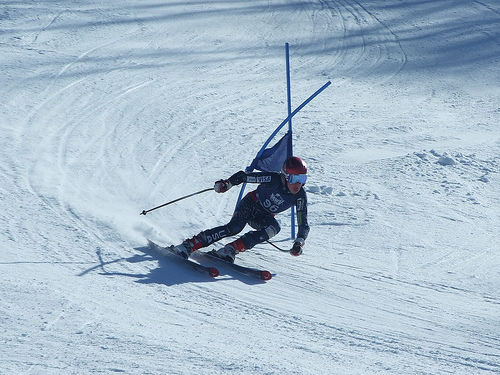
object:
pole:
[136, 185, 226, 219]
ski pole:
[138, 180, 216, 239]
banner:
[237, 41, 331, 194]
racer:
[167, 156, 310, 263]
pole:
[266, 236, 293, 254]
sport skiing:
[388, 76, 475, 221]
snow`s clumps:
[308, 144, 498, 216]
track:
[304, 0, 407, 91]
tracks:
[35, 88, 178, 184]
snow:
[339, 65, 481, 310]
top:
[234, 171, 317, 230]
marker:
[193, 122, 347, 251]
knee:
[269, 222, 281, 233]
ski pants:
[182, 195, 281, 269]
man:
[174, 154, 310, 261]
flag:
[247, 129, 292, 174]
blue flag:
[247, 129, 292, 173]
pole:
[283, 41, 296, 238]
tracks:
[10, 55, 193, 185]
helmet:
[284, 156, 312, 183]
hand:
[211, 174, 234, 196]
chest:
[236, 177, 312, 237]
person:
[192, 156, 322, 278]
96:
[262, 197, 278, 214]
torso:
[253, 177, 291, 212]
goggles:
[280, 172, 307, 184]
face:
[284, 175, 302, 194]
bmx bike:
[19, 47, 144, 210]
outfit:
[182, 169, 311, 251]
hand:
[286, 242, 308, 257]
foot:
[210, 247, 235, 263]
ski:
[220, 247, 270, 275]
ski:
[147, 239, 215, 278]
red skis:
[192, 249, 277, 281]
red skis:
[145, 240, 217, 275]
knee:
[224, 222, 247, 236]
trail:
[17, 4, 496, 366]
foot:
[168, 242, 187, 254]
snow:
[1, 2, 181, 215]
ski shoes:
[144, 240, 199, 268]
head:
[282, 152, 307, 196]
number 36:
[263, 198, 279, 213]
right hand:
[212, 177, 231, 195]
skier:
[170, 155, 311, 265]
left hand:
[286, 241, 306, 258]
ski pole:
[266, 239, 292, 256]